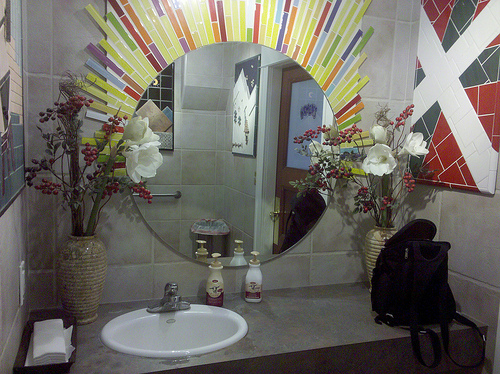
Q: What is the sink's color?
A: White.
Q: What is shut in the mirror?
A: Door.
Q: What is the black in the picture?
A: Bag.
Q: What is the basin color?
A: White.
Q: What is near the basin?
A: Flowers.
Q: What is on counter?
A: Black bag.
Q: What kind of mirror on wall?
A: Round.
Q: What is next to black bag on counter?
A: Tile.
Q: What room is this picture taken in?
A: A bathroom.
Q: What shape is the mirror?
A: Round.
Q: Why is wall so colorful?
A: To be artsy.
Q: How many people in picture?
A: None.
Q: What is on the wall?
A: A mirror.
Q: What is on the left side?
A: A sink.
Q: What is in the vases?
A: Flowers.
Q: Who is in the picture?
A: No one.